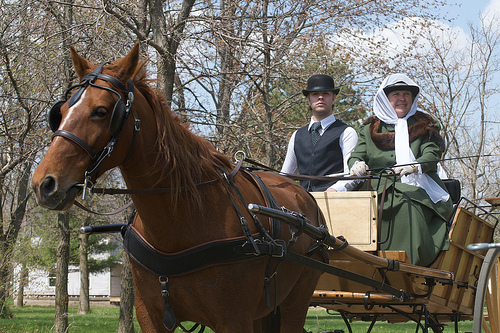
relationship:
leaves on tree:
[278, 52, 362, 125] [238, 38, 358, 128]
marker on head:
[53, 80, 85, 143] [20, 30, 165, 213]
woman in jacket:
[344, 71, 457, 273] [365, 126, 445, 266]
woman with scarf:
[352, 67, 458, 272] [371, 70, 451, 202]